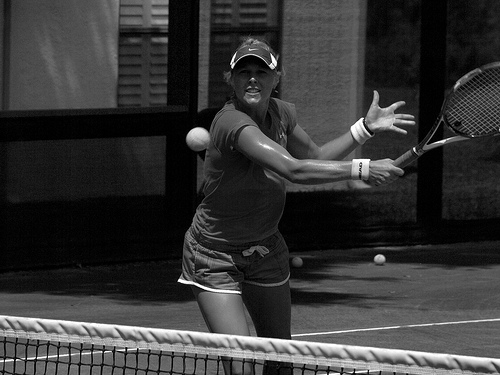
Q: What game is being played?
A: Tennis.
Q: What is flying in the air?
A: Ball.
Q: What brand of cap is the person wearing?
A: Nike.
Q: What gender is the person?
A: Female.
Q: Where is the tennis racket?
A: Right hand.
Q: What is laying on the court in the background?
A: Balls.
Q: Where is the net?
A: Bottom of the image.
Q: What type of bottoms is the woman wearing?
A: Shorts.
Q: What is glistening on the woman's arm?
A: Sweat.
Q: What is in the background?
A: Wall.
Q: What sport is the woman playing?
A: Tennis.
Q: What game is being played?
A: Tennis.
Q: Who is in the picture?
A: A woman.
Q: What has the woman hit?
A: A ball.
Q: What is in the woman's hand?
A: A tennis racket.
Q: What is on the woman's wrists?
A: Sweat bands.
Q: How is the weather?
A: Sunny.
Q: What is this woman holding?
A: A tennis racket.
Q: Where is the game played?
A: A tennis court.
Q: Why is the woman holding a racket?
A: To hit the ball.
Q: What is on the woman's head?
A: A hat.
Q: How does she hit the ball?
A: With the tennis racket.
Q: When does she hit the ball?
A: When it is on her side.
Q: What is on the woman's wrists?
A: Sweat bands.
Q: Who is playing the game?
A: A tennis player.